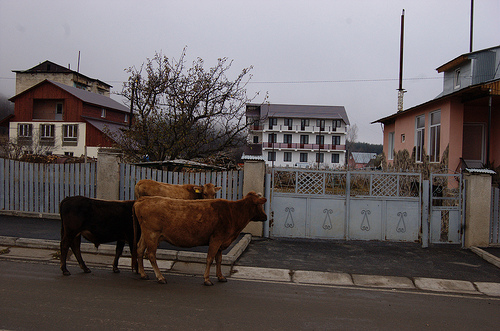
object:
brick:
[14, 98, 34, 122]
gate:
[264, 163, 422, 242]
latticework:
[313, 187, 319, 194]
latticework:
[377, 188, 383, 192]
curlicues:
[395, 211, 407, 233]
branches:
[195, 111, 221, 119]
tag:
[194, 187, 202, 193]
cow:
[135, 178, 223, 199]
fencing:
[1, 157, 98, 215]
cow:
[57, 195, 142, 276]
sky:
[0, 0, 499, 145]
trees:
[98, 45, 276, 173]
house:
[7, 78, 148, 157]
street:
[1, 258, 499, 330]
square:
[231, 265, 292, 283]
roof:
[46, 79, 143, 116]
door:
[430, 165, 462, 244]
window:
[283, 117, 291, 126]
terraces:
[329, 133, 346, 149]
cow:
[133, 191, 268, 286]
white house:
[241, 102, 350, 170]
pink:
[394, 117, 405, 129]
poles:
[469, 0, 473, 52]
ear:
[192, 186, 204, 193]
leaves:
[123, 68, 127, 72]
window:
[299, 152, 303, 162]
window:
[336, 136, 341, 146]